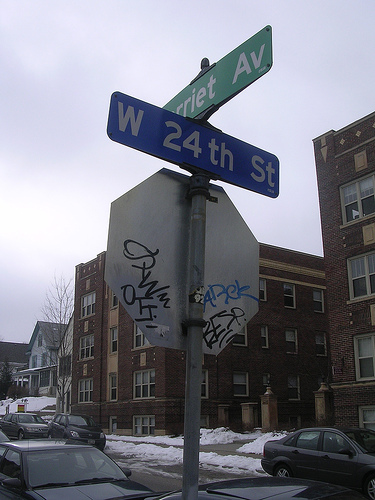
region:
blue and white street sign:
[135, 108, 250, 191]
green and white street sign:
[178, 61, 294, 102]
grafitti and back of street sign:
[115, 189, 276, 369]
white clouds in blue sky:
[9, 12, 57, 75]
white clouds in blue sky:
[3, 52, 54, 113]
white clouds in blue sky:
[52, 96, 75, 155]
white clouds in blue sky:
[7, 145, 90, 206]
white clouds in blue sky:
[8, 193, 62, 238]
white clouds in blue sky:
[297, 38, 343, 82]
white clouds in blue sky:
[100, 19, 164, 55]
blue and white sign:
[120, 105, 282, 189]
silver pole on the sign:
[175, 379, 229, 460]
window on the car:
[324, 430, 348, 459]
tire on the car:
[272, 457, 293, 481]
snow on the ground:
[233, 437, 260, 473]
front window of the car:
[31, 448, 105, 497]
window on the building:
[127, 366, 158, 394]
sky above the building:
[27, 87, 80, 137]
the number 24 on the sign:
[158, 118, 208, 165]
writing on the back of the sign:
[132, 246, 169, 299]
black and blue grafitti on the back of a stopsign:
[109, 236, 263, 351]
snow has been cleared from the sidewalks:
[100, 424, 286, 467]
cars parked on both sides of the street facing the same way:
[1, 414, 374, 498]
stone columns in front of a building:
[213, 380, 335, 432]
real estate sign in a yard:
[10, 397, 30, 420]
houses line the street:
[3, 316, 72, 421]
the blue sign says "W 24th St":
[107, 92, 296, 203]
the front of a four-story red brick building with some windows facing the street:
[64, 242, 175, 440]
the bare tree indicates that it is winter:
[40, 276, 81, 429]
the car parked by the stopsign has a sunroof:
[179, 469, 311, 498]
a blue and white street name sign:
[106, 88, 280, 195]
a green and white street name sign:
[162, 24, 271, 116]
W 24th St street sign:
[107, 88, 279, 196]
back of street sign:
[102, 168, 261, 357]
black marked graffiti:
[118, 235, 171, 331]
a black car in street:
[260, 421, 374, 496]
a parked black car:
[0, 438, 152, 498]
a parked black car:
[157, 473, 373, 498]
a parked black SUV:
[47, 409, 104, 449]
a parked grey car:
[0, 409, 47, 440]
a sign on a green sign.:
[163, 15, 285, 117]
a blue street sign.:
[99, 89, 285, 200]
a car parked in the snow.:
[255, 414, 373, 498]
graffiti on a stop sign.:
[112, 221, 175, 356]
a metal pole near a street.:
[178, 43, 220, 497]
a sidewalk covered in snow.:
[102, 423, 349, 481]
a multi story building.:
[16, 319, 79, 398]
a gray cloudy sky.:
[3, 1, 373, 344]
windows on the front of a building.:
[123, 366, 165, 406]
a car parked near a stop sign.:
[0, 431, 160, 499]